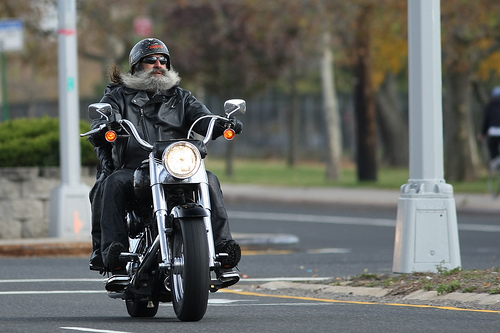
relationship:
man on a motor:
[86, 36, 246, 273] [78, 96, 247, 323]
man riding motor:
[86, 36, 244, 274] [78, 98, 247, 321]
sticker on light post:
[55, 26, 76, 39] [47, 5, 103, 246]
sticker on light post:
[62, 77, 82, 93] [47, 5, 103, 246]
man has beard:
[86, 36, 244, 274] [116, 67, 184, 95]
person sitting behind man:
[84, 70, 125, 272] [86, 36, 244, 274]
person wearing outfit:
[479, 84, 497, 169] [482, 97, 498, 160]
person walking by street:
[479, 84, 497, 169] [1, 188, 496, 329]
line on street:
[225, 283, 499, 323] [1, 188, 496, 329]